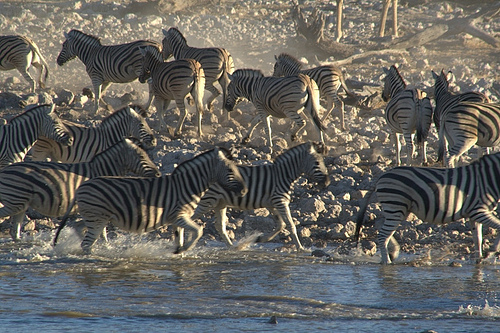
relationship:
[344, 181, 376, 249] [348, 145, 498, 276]
tail of zebra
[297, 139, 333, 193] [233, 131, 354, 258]
head of zebra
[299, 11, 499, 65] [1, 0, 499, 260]
drift wood lying on fields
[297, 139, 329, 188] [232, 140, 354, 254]
head of a zebra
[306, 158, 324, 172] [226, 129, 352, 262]
eye of a zebra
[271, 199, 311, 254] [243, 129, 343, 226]
leg of a zebra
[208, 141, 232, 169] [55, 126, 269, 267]
ear of a zebra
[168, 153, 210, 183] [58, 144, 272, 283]
mane of a zebra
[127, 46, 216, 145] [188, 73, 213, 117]
zebra with tail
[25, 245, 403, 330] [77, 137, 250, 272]
river with zebra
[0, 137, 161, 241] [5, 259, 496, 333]
zebras in water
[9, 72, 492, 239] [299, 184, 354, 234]
zebras on rocks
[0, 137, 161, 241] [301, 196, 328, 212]
zebras on rock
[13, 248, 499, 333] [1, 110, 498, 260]
water behind fields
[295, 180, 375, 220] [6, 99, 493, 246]
rocks on ground